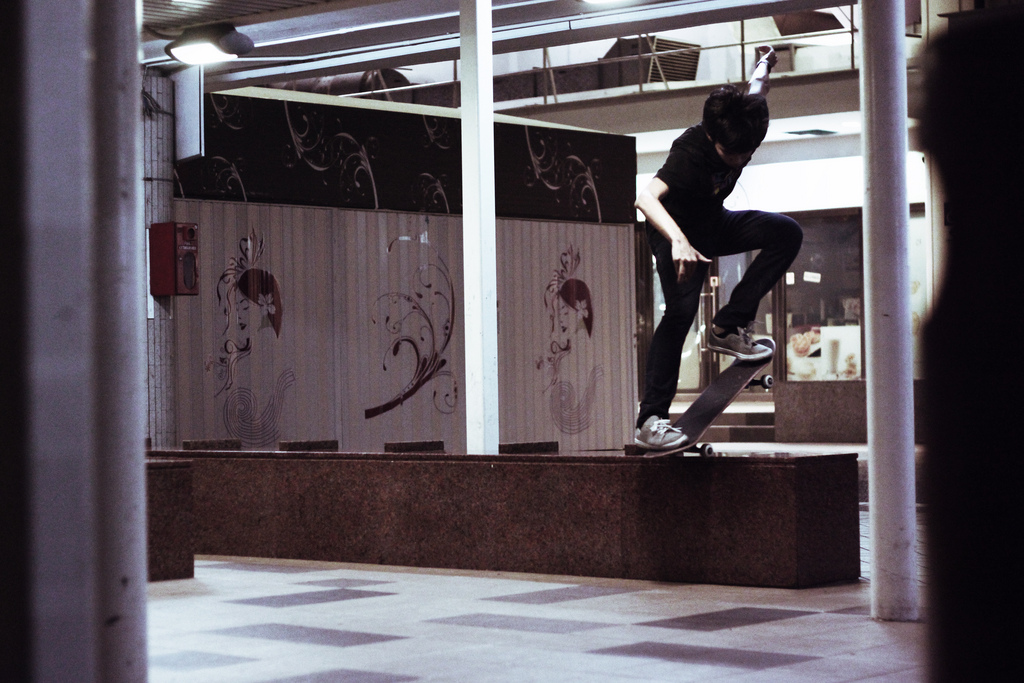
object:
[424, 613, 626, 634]
tile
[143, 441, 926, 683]
floor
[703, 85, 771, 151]
hair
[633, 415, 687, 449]
shoe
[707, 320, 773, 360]
shoe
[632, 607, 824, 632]
tile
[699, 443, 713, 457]
wheel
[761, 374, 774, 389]
wheel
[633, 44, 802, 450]
guy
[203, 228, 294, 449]
design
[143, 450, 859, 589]
fixture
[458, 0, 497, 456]
post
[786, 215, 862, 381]
window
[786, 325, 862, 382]
posters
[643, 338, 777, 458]
skateboard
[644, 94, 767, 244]
shirt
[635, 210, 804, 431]
pants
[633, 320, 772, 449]
shoes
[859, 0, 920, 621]
pole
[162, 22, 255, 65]
light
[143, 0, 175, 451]
side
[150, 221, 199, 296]
box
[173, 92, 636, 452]
wall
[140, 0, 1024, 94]
ceiling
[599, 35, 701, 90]
air vent